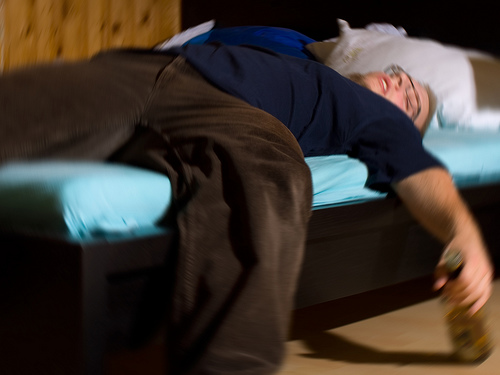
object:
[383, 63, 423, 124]
eyeglasses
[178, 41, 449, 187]
shirt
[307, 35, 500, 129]
pillow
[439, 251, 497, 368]
bottle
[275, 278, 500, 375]
floor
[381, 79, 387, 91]
teeth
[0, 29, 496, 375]
man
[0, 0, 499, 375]
photo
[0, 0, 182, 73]
wall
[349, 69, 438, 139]
head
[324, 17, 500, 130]
case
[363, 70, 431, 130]
face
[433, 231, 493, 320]
hand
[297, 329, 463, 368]
shadow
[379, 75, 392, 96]
mouth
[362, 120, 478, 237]
arm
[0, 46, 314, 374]
jeans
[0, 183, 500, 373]
frame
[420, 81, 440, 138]
hair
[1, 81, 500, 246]
bed sheet